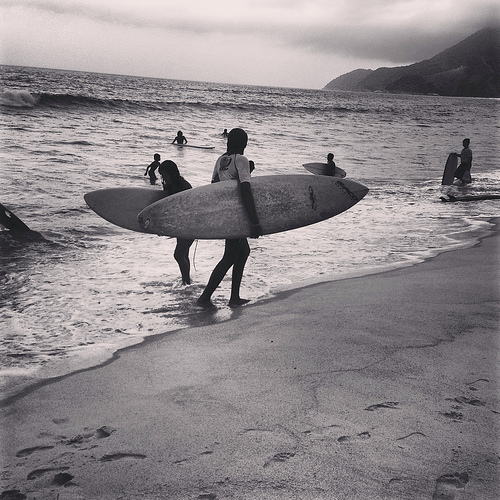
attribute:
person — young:
[142, 150, 164, 185]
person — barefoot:
[195, 124, 253, 309]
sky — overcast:
[4, 1, 476, 59]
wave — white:
[0, 86, 35, 107]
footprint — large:
[428, 467, 467, 498]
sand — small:
[193, 385, 383, 493]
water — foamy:
[1, 89, 37, 107]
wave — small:
[3, 86, 354, 122]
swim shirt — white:
[213, 150, 250, 184]